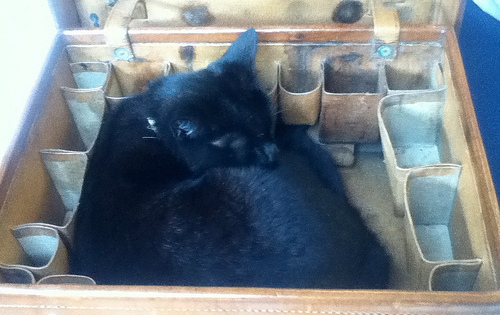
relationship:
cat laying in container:
[70, 23, 399, 290] [4, 30, 499, 314]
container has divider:
[4, 30, 499, 314] [321, 57, 380, 142]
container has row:
[4, 30, 499, 314] [374, 42, 498, 293]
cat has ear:
[70, 23, 399, 290] [210, 26, 261, 90]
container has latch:
[4, 30, 499, 314] [369, 3, 402, 67]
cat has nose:
[70, 23, 399, 290] [261, 143, 284, 169]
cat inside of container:
[70, 23, 399, 290] [4, 30, 499, 314]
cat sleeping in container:
[70, 23, 399, 290] [4, 30, 499, 314]